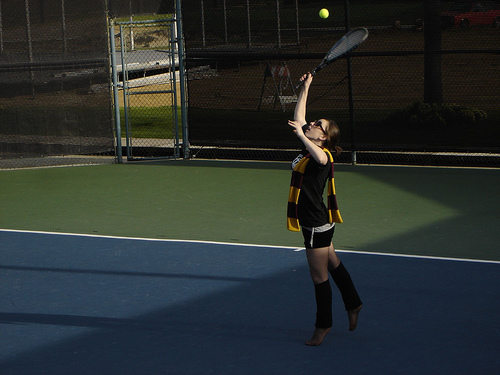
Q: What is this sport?
A: Tennis.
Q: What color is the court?
A: Blue.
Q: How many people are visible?
A: One.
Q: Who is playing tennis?
A: The woman.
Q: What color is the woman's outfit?
A: Black.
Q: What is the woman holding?
A: Racket.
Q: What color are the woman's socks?
A: Black.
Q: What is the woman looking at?
A: The ball.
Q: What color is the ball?
A: Bright green.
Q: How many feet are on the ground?
A: One.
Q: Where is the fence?
A: Around the tennis court.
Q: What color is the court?
A: Blue.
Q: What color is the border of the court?
A: Green.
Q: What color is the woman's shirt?
A: Black.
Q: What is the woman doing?
A: Hitting a ball.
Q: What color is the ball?
A: Yellow.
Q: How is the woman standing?
A: On her tiptoes.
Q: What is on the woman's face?
A: Sunglasses.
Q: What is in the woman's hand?
A: A racquet.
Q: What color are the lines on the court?
A: White.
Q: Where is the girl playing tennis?
A: On the tennis court.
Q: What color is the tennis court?
A: Blue, white, and green.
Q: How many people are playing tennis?
A: One.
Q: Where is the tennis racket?
A: In the girls hand.